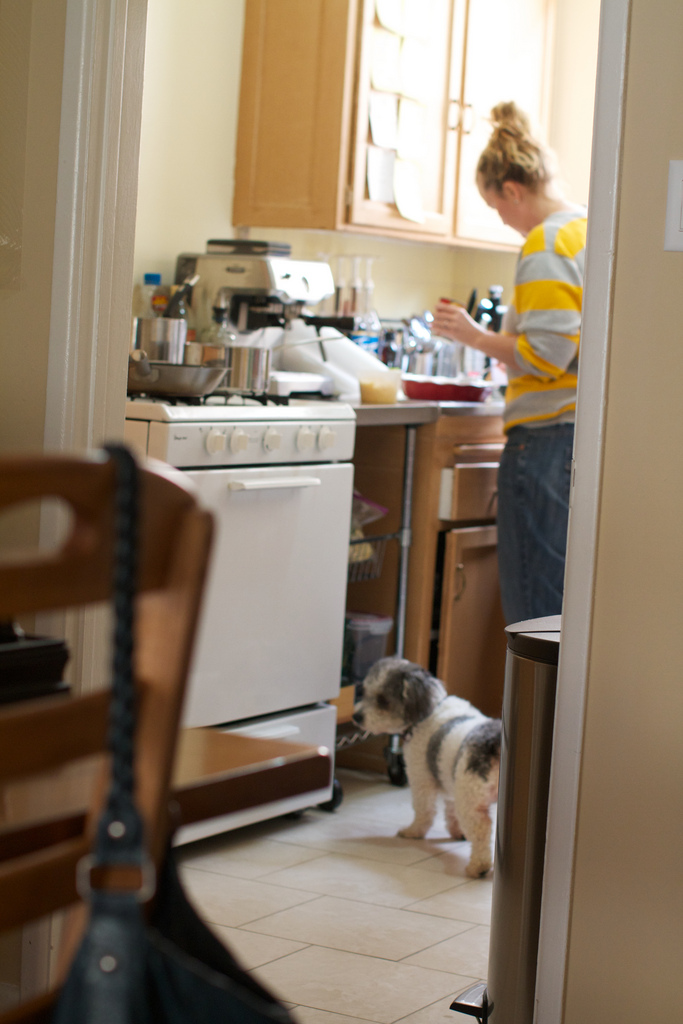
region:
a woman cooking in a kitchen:
[426, 103, 589, 633]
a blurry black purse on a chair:
[53, 436, 296, 1022]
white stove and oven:
[120, 389, 356, 843]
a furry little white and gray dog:
[349, 656, 503, 877]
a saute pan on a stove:
[129, 347, 228, 397]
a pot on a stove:
[182, 329, 349, 391]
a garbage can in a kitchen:
[446, 612, 542, 1022]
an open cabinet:
[426, 522, 503, 724]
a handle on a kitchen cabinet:
[453, 561, 466, 601]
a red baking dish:
[405, 366, 496, 403]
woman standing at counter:
[435, 94, 586, 776]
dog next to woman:
[349, 661, 525, 898]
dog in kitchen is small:
[347, 655, 511, 888]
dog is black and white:
[347, 647, 525, 897]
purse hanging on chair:
[61, 431, 291, 1022]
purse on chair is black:
[63, 432, 332, 1021]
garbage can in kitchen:
[450, 603, 583, 1021]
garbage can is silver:
[448, 616, 565, 1020]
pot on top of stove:
[179, 330, 268, 408]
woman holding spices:
[426, 293, 460, 346]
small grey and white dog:
[353, 658, 501, 874]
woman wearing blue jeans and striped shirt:
[432, 99, 586, 621]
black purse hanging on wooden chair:
[1, 441, 296, 1022]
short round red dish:
[401, 371, 491, 400]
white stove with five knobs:
[126, 389, 358, 848]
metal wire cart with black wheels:
[323, 407, 439, 809]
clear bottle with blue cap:
[138, 270, 160, 313]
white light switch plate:
[665, 166, 681, 253]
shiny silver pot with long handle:
[184, 330, 346, 392]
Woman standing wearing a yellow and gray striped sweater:
[437, 91, 598, 867]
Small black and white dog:
[341, 651, 522, 883]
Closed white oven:
[124, 391, 350, 855]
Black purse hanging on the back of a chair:
[21, 438, 288, 1019]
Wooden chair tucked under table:
[0, 436, 220, 1021]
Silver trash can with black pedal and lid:
[452, 604, 551, 1019]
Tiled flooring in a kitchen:
[72, 760, 505, 1021]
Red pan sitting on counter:
[403, 368, 494, 408]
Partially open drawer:
[435, 456, 528, 524]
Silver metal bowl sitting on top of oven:
[119, 346, 245, 414]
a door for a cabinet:
[457, 11, 531, 250]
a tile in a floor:
[287, 791, 439, 866]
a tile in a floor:
[202, 817, 299, 874]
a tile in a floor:
[284, 836, 443, 910]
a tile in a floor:
[182, 856, 285, 929]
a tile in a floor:
[280, 886, 449, 975]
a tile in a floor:
[249, 932, 434, 1022]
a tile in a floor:
[190, 889, 301, 970]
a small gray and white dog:
[348, 654, 499, 880]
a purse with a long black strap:
[48, 436, 302, 1020]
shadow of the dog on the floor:
[330, 831, 496, 903]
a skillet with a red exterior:
[401, 374, 506, 402]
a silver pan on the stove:
[129, 345, 235, 399]